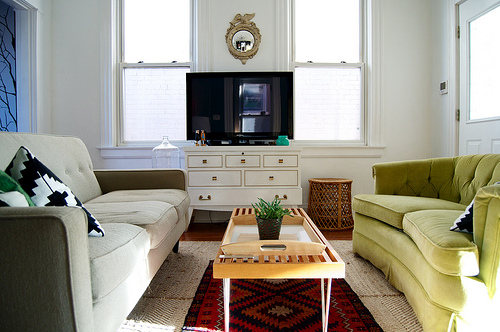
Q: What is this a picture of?
A: A living room.